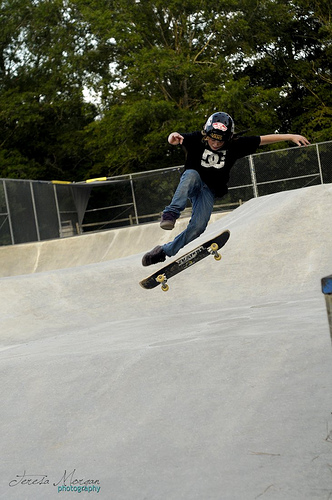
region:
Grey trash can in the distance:
[58, 217, 75, 237]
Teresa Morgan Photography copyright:
[7, 470, 104, 498]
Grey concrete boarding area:
[16, 296, 306, 463]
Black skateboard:
[136, 226, 231, 291]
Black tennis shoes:
[121, 200, 177, 264]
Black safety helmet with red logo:
[201, 110, 235, 138]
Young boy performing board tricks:
[77, 109, 309, 293]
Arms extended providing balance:
[157, 118, 314, 150]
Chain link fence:
[14, 180, 143, 222]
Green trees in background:
[96, 28, 325, 104]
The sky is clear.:
[0, 0, 331, 135]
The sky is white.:
[0, 0, 331, 134]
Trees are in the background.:
[0, 0, 329, 247]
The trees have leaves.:
[0, 0, 331, 246]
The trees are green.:
[0, 0, 330, 247]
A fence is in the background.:
[0, 138, 330, 249]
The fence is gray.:
[0, 139, 329, 244]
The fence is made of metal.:
[0, 137, 331, 247]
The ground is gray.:
[0, 182, 331, 499]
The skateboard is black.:
[139, 227, 231, 291]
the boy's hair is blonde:
[200, 129, 209, 141]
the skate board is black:
[136, 230, 232, 292]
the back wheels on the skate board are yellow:
[152, 271, 170, 292]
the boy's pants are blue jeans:
[161, 169, 214, 262]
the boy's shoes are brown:
[139, 208, 178, 267]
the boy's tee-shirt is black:
[180, 132, 259, 200]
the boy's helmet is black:
[202, 111, 235, 141]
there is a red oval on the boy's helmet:
[210, 121, 228, 131]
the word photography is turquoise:
[57, 485, 101, 494]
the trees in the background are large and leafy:
[0, 2, 330, 204]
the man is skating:
[136, 111, 312, 272]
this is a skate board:
[130, 226, 239, 301]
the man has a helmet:
[189, 108, 253, 158]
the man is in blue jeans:
[153, 161, 215, 257]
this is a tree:
[81, 2, 230, 174]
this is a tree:
[5, 70, 89, 227]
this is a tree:
[118, 45, 212, 211]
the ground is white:
[139, 362, 225, 451]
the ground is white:
[62, 376, 156, 457]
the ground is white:
[258, 373, 311, 465]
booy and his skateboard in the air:
[127, 114, 311, 302]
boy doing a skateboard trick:
[126, 116, 312, 308]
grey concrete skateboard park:
[34, 226, 131, 398]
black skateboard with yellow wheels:
[138, 227, 239, 295]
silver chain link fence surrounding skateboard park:
[18, 140, 310, 241]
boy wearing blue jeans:
[143, 166, 223, 267]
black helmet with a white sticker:
[202, 110, 234, 152]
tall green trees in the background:
[35, 16, 296, 169]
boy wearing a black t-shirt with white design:
[167, 122, 278, 187]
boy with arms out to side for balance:
[135, 125, 328, 299]